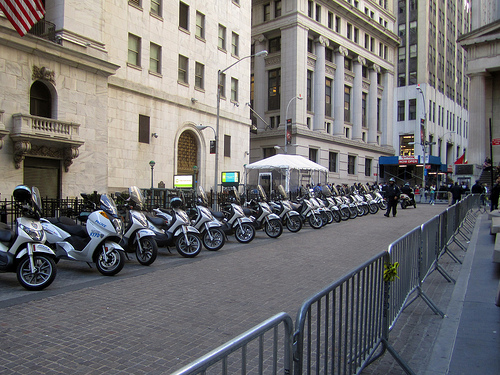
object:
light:
[203, 42, 278, 202]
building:
[394, 0, 466, 171]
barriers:
[117, 165, 499, 372]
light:
[415, 77, 426, 105]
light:
[273, 77, 306, 126]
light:
[221, 35, 296, 68]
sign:
[396, 152, 423, 171]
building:
[251, 0, 451, 204]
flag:
[1, 0, 52, 39]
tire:
[88, 237, 130, 277]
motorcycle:
[36, 191, 183, 275]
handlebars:
[11, 189, 43, 217]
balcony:
[12, 109, 89, 139]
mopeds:
[236, 181, 364, 236]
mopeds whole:
[239, 172, 329, 237]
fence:
[164, 188, 486, 373]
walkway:
[3, 197, 458, 373]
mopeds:
[3, 184, 385, 291]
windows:
[281, 73, 381, 132]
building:
[60, 17, 488, 244]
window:
[223, 73, 248, 106]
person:
[378, 173, 406, 220]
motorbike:
[44, 193, 129, 277]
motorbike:
[145, 196, 203, 258]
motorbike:
[208, 193, 256, 244]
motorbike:
[274, 193, 304, 234]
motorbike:
[320, 186, 344, 226]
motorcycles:
[0, 174, 357, 296]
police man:
[378, 174, 403, 219]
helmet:
[386, 174, 394, 184]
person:
[398, 180, 419, 210]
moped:
[397, 192, 417, 211]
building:
[252, 7, 490, 192]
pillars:
[304, 59, 387, 133]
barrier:
[295, 213, 486, 373]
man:
[385, 175, 401, 217]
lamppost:
[145, 147, 155, 194]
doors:
[166, 118, 212, 186]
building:
[104, 3, 251, 185]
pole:
[212, 48, 231, 198]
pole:
[282, 91, 305, 155]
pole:
[413, 82, 429, 202]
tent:
[238, 142, 332, 192]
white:
[241, 142, 310, 168]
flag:
[453, 148, 470, 165]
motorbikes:
[78, 180, 390, 281]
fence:
[381, 195, 465, 342]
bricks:
[243, 216, 388, 292]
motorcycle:
[398, 182, 415, 203]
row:
[4, 183, 390, 293]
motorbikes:
[6, 181, 158, 285]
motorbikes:
[158, 185, 255, 252]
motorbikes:
[251, 177, 328, 237]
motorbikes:
[322, 180, 385, 218]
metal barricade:
[337, 286, 359, 308]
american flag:
[0, 0, 53, 40]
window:
[27, 76, 63, 117]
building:
[5, 2, 213, 183]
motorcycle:
[34, 202, 127, 279]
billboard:
[214, 164, 254, 193]